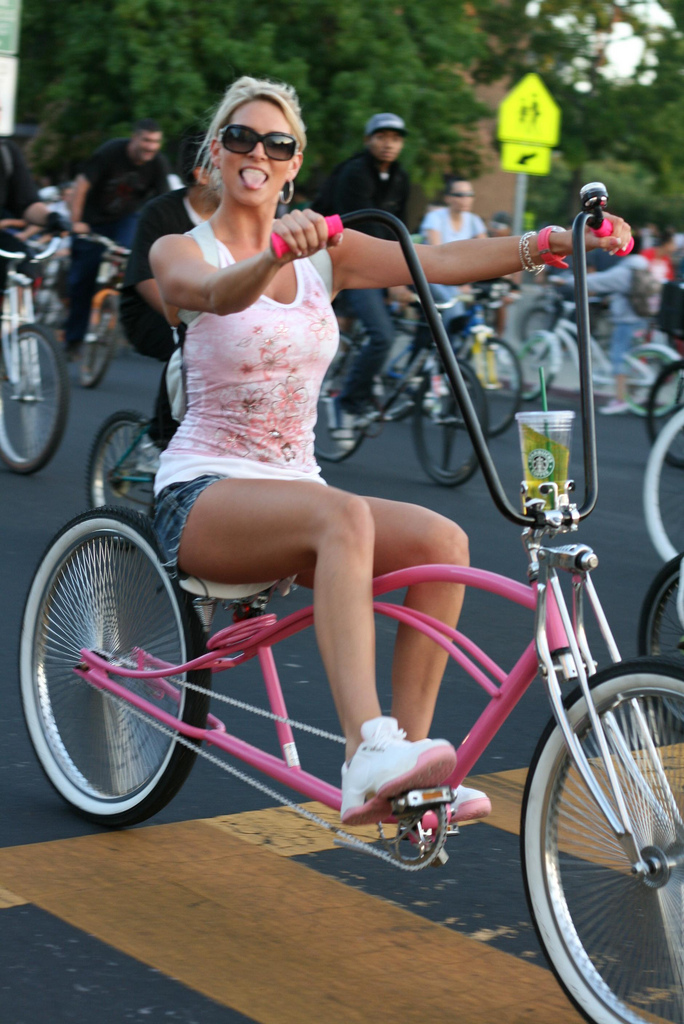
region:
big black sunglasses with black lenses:
[217, 121, 297, 162]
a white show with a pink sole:
[337, 718, 459, 820]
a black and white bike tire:
[17, 498, 212, 829]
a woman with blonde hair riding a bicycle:
[18, 76, 678, 1012]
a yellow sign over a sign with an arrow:
[494, 73, 557, 181]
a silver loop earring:
[278, 173, 294, 205]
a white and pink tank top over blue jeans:
[156, 219, 337, 580]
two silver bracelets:
[517, 229, 546, 274]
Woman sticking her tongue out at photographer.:
[201, 71, 310, 211]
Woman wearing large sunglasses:
[199, 73, 317, 208]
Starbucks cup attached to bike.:
[509, 403, 584, 511]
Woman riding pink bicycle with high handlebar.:
[16, 76, 671, 1013]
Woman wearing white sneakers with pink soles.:
[332, 721, 495, 828]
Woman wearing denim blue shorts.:
[142, 469, 229, 580]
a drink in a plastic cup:
[505, 361, 592, 540]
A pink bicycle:
[27, 281, 680, 842]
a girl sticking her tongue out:
[167, 42, 338, 271]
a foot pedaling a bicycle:
[328, 712, 471, 894]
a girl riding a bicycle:
[49, 99, 625, 1003]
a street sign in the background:
[487, 50, 572, 405]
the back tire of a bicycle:
[24, 510, 220, 857]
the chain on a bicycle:
[68, 656, 344, 837]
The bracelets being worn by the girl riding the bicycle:
[506, 219, 600, 278]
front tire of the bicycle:
[523, 632, 674, 1017]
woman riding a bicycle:
[133, 69, 641, 854]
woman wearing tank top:
[146, 202, 341, 491]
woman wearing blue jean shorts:
[140, 456, 234, 579]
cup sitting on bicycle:
[505, 366, 588, 516]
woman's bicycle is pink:
[20, 183, 682, 1019]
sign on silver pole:
[483, 56, 568, 179]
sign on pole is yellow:
[490, 63, 563, 181]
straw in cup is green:
[536, 358, 563, 502]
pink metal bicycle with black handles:
[15, 177, 678, 1020]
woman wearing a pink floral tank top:
[145, 71, 636, 825]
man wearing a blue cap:
[316, 111, 415, 416]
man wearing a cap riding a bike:
[319, 109, 491, 487]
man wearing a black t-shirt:
[62, 114, 170, 389]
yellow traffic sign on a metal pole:
[494, 66, 561, 232]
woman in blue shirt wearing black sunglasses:
[418, 176, 494, 239]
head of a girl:
[120, 62, 365, 256]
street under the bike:
[74, 852, 334, 993]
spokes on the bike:
[523, 811, 671, 974]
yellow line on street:
[27, 825, 327, 1020]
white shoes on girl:
[254, 674, 504, 856]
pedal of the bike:
[363, 760, 482, 842]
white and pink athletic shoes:
[334, 713, 496, 831]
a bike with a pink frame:
[17, 203, 679, 1015]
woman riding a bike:
[138, 69, 632, 835]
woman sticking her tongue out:
[189, 75, 313, 211]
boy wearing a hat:
[318, 110, 418, 232]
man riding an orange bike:
[68, 116, 174, 385]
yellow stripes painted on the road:
[0, 733, 683, 1015]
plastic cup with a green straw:
[515, 364, 580, 516]